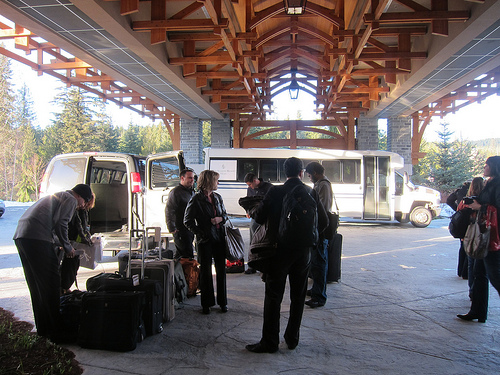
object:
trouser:
[262, 252, 289, 349]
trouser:
[283, 250, 311, 349]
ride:
[202, 147, 442, 227]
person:
[182, 170, 246, 315]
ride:
[39, 149, 185, 250]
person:
[448, 155, 500, 323]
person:
[12, 183, 92, 341]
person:
[305, 161, 340, 307]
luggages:
[59, 226, 201, 352]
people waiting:
[11, 154, 500, 354]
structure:
[0, 0, 499, 146]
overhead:
[0, 0, 499, 121]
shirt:
[12, 190, 78, 254]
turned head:
[196, 170, 220, 192]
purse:
[219, 214, 245, 263]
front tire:
[409, 205, 433, 227]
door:
[142, 149, 186, 238]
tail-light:
[130, 171, 142, 192]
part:
[310, 239, 328, 301]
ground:
[176, 316, 244, 375]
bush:
[412, 119, 488, 203]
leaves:
[432, 154, 470, 180]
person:
[165, 169, 197, 259]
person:
[244, 172, 273, 219]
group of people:
[238, 157, 330, 353]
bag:
[463, 209, 493, 259]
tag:
[132, 274, 140, 286]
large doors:
[363, 154, 391, 218]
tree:
[13, 120, 44, 203]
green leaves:
[16, 178, 36, 202]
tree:
[115, 121, 145, 154]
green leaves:
[121, 134, 139, 151]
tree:
[48, 80, 110, 155]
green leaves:
[54, 126, 96, 152]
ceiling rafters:
[118, 0, 472, 122]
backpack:
[275, 182, 320, 249]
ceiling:
[254, 0, 328, 116]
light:
[289, 79, 300, 99]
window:
[341, 159, 361, 184]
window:
[322, 160, 341, 183]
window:
[238, 160, 259, 183]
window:
[259, 159, 279, 182]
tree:
[426, 119, 489, 193]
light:
[283, 0, 307, 16]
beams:
[119, 0, 484, 122]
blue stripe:
[217, 187, 247, 190]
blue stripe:
[219, 184, 247, 186]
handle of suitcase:
[127, 229, 145, 280]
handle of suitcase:
[145, 226, 161, 260]